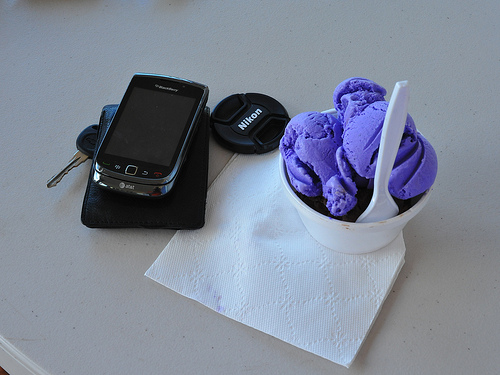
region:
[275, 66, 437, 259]
blue sherbert in a bowl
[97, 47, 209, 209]
a blackberry smartphone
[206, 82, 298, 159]
a nikon camera lens cover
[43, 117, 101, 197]
a chevy car key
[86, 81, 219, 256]
black leather wallet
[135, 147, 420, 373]
white paper nampkin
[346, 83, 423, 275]
a white plastic spoon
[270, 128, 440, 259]
a round white styrofoam cup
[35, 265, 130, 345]
a white table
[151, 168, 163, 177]
a red end call button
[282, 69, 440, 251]
a cup of frozen yogurt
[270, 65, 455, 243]
a cup of ice cream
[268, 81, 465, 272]
a white foam cup of ice cream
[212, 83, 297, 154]
a black lens cap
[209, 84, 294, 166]
a Nikon brand lens cap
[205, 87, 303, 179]
a camera lens cap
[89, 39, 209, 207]
A Blackberry cell phone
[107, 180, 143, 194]
the AT&T logo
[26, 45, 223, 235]
a phone on top of a wallet which is on top of a car key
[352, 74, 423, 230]
a plastic spoon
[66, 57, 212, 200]
a silver cell phone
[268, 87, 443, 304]
a white styrofoam cup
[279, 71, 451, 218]
purple icecream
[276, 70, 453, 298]
purple icecream in a white cup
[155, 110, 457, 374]
a white paper napkin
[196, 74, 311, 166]
a black nikon camera lens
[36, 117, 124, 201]
a black car key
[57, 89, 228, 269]
a black wallet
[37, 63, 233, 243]
a cellphone a key and a wallet on a table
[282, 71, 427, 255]
cup of ice cream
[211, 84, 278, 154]
a camera cap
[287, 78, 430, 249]
blue colored ice cream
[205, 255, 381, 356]
a white printed napkin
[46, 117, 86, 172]
a black car key next to a phone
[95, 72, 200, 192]
a cell phone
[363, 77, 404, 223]
a white spoon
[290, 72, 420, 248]
a spoon inside a cup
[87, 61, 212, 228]
a cell phone and wallet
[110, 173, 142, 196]
an at&t logo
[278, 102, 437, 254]
White bowl on the table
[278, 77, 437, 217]
Ice cream in the bowl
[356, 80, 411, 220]
Spoon in the bowl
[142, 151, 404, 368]
Napkin on the table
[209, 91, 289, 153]
Camera lens cap on the table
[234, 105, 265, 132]
Brand name on the camera lens cap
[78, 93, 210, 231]
Wallet on the table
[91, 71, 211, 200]
Cellphone on the wallet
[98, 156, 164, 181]
Buttons on the cellphone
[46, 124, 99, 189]
Key on the table